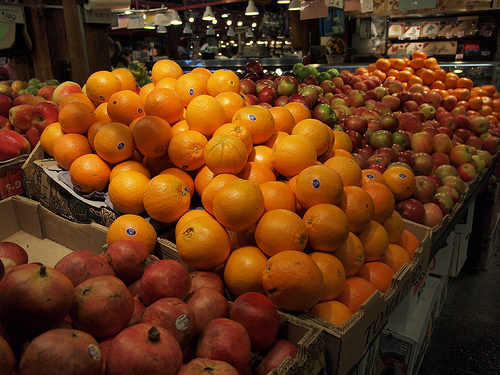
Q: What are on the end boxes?
A: Tangerines.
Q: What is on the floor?
A: Boxes.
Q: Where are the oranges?
A: In a pile.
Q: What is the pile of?
A: Oranges.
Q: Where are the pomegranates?
A: In a box.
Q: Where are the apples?
A: Next to the oranges.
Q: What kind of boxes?
A: Cardboard.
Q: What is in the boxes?
A: Fruit.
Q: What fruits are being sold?
A: Pomegranates, oranges, and apples.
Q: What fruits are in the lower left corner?
A: Pomegranates.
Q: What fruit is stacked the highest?
A: Oranges.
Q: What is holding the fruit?
A: Cardboard bins.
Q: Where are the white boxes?
A: Under the fruit.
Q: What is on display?
A: Fruits.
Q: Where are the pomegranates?
A: Lower left corner.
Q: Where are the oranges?
A: Between the apples and pomegranates.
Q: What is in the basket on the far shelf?
A: Orange flowers.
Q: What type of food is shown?
A: Fruit.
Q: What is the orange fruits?
A: Oranges.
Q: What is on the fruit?
A: Sticker.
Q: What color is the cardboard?
A: Brown.